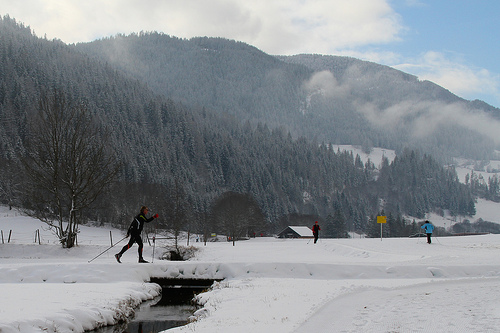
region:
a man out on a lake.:
[109, 191, 157, 273]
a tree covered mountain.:
[2, 12, 498, 235]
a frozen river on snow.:
[61, 214, 79, 251]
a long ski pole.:
[85, 227, 126, 267]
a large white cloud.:
[398, 48, 494, 113]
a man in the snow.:
[305, 222, 323, 243]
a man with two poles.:
[80, 200, 170, 275]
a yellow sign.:
[367, 210, 389, 235]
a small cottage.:
[277, 220, 317, 240]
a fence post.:
[2, 225, 17, 262]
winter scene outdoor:
[3, 8, 496, 326]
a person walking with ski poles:
[80, 200, 165, 265]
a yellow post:
[373, 212, 389, 241]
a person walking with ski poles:
[303, 218, 325, 248]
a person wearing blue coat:
[416, 215, 440, 245]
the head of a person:
[138, 202, 150, 217]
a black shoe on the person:
[136, 253, 151, 265]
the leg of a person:
[134, 236, 149, 259]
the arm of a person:
[143, 211, 158, 226]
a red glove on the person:
[151, 207, 161, 222]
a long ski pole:
[84, 232, 130, 266]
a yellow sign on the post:
[371, 208, 391, 226]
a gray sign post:
[377, 220, 383, 239]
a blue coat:
[420, 220, 438, 235]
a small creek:
[86, 272, 224, 331]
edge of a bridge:
[177, 262, 206, 287]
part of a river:
[153, 296, 184, 329]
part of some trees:
[204, 129, 269, 181]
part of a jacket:
[420, 222, 434, 235]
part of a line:
[297, 297, 316, 319]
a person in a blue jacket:
[417, 215, 441, 245]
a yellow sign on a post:
[372, 210, 393, 239]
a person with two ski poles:
[89, 197, 169, 266]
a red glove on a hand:
[151, 206, 165, 223]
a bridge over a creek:
[126, 258, 239, 295]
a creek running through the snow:
[78, 246, 255, 330]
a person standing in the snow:
[305, 216, 330, 250]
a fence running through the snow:
[1, 216, 255, 250]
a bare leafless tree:
[11, 81, 127, 263]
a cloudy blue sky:
[24, 4, 491, 99]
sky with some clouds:
[13, 4, 497, 109]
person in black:
[114, 191, 176, 281]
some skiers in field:
[83, 141, 465, 286]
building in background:
[256, 201, 357, 263]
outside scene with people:
[2, 2, 497, 329]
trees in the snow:
[5, 9, 496, 248]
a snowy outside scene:
[10, 22, 499, 331]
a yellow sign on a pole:
[364, 192, 413, 272]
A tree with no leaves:
[13, 78, 116, 273]